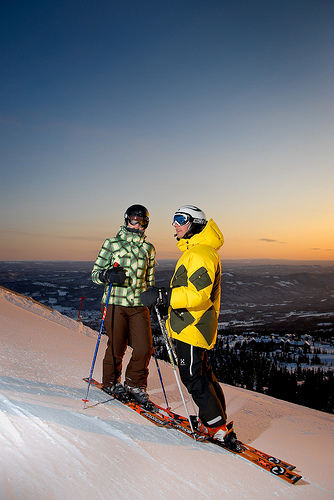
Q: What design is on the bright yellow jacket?
A: Diamond shapes.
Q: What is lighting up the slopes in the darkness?
A: Artificial lights.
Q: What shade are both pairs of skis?
A: Orange.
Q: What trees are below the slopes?
A: Pine trees.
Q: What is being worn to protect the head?
A: Helmets.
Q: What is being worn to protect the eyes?
A: Goggles.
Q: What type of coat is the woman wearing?
A: Green and white plaid.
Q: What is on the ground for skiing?
A: Snow.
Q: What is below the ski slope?
A: A pretty valley.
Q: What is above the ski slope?
A: The night sky.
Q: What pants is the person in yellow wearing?
A: Black.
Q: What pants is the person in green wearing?
A: Brown.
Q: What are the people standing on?
A: Skis.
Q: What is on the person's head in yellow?
A: A helmet.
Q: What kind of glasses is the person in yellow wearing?
A: Snow goggles.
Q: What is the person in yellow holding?
A: Ski poles.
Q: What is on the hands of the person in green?
A: Gloves.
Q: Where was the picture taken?
A: Mountain.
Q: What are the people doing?
A: Skiing.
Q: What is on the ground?
A: Snow.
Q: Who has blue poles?
A: Woman.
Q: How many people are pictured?
A: 2.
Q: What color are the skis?
A: Orange.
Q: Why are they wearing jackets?
A: Cold.